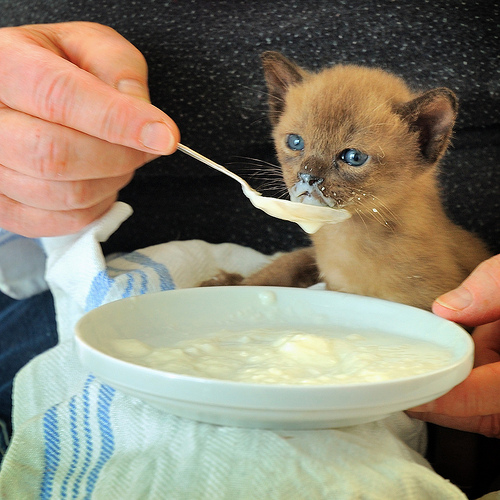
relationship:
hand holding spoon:
[0, 16, 183, 239] [167, 137, 355, 234]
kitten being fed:
[258, 49, 500, 311] [290, 175, 337, 217]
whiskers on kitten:
[337, 182, 397, 231] [258, 49, 500, 311]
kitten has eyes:
[258, 49, 500, 311] [286, 134, 373, 170]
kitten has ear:
[258, 49, 500, 311] [398, 81, 462, 171]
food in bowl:
[111, 329, 458, 392] [72, 284, 483, 435]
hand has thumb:
[0, 16, 183, 239] [50, 20, 153, 106]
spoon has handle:
[167, 137, 355, 234] [176, 143, 251, 186]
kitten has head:
[258, 49, 500, 311] [265, 65, 434, 220]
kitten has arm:
[258, 49, 500, 311] [195, 247, 325, 294]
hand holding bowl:
[0, 16, 183, 239] [72, 284, 483, 435]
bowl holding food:
[72, 284, 483, 435] [111, 329, 458, 392]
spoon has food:
[167, 137, 355, 234] [111, 329, 458, 392]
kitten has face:
[258, 49, 500, 311] [278, 129, 379, 206]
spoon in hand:
[167, 137, 355, 234] [0, 16, 183, 239]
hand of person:
[0, 16, 183, 239] [0, 50, 212, 366]